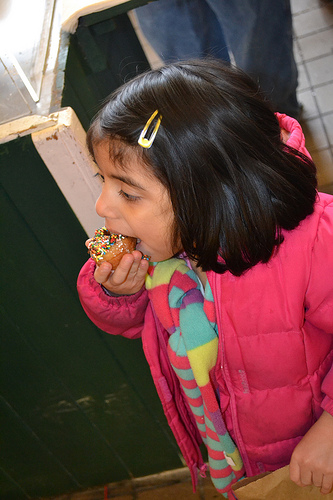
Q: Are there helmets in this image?
A: No, there are no helmets.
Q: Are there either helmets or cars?
A: No, there are no helmets or cars.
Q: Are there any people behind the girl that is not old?
A: Yes, there is a person behind the girl.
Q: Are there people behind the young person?
A: Yes, there is a person behind the girl.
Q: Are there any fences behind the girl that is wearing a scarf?
A: No, there is a person behind the girl.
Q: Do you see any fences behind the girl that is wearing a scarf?
A: No, there is a person behind the girl.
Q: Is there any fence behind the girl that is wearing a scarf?
A: No, there is a person behind the girl.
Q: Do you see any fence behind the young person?
A: No, there is a person behind the girl.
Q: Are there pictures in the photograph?
A: No, there are no pictures.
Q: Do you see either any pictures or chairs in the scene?
A: No, there are no pictures or chairs.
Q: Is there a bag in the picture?
A: Yes, there is a bag.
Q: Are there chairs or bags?
A: Yes, there is a bag.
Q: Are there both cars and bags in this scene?
A: No, there is a bag but no cars.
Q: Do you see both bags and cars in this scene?
A: No, there is a bag but no cars.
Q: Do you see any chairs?
A: No, there are no chairs.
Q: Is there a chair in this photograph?
A: No, there are no chairs.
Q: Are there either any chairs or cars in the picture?
A: No, there are no chairs or cars.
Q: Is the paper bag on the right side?
A: Yes, the bag is on the right of the image.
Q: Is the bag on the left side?
A: No, the bag is on the right of the image.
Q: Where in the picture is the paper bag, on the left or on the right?
A: The bag is on the right of the image.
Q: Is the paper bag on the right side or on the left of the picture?
A: The bag is on the right of the image.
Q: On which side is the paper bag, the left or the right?
A: The bag is on the right of the image.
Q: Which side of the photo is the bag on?
A: The bag is on the right of the image.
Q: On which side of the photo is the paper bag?
A: The bag is on the right of the image.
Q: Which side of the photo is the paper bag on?
A: The bag is on the right of the image.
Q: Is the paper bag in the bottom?
A: Yes, the bag is in the bottom of the image.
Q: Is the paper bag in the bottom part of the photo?
A: Yes, the bag is in the bottom of the image.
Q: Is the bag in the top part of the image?
A: No, the bag is in the bottom of the image.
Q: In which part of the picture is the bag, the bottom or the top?
A: The bag is in the bottom of the image.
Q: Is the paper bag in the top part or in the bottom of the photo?
A: The bag is in the bottom of the image.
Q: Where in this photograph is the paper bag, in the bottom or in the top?
A: The bag is in the bottom of the image.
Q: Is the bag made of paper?
A: Yes, the bag is made of paper.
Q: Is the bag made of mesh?
A: No, the bag is made of paper.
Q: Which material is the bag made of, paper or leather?
A: The bag is made of paper.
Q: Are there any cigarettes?
A: No, there are no cigarettes.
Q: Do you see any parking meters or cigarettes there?
A: No, there are no cigarettes or parking meters.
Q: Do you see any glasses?
A: No, there are no glasses.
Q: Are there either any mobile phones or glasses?
A: No, there are no glasses or mobile phones.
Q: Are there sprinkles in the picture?
A: Yes, there are sprinkles.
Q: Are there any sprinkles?
A: Yes, there are sprinkles.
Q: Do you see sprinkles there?
A: Yes, there are sprinkles.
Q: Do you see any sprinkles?
A: Yes, there are sprinkles.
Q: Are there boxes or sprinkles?
A: Yes, there are sprinkles.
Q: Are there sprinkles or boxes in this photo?
A: Yes, there are sprinkles.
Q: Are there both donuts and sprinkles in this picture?
A: Yes, there are both sprinkles and a donut.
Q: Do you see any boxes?
A: No, there are no boxes.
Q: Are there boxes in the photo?
A: No, there are no boxes.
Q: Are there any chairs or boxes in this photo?
A: No, there are no boxes or chairs.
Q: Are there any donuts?
A: Yes, there is a donut.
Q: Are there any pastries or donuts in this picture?
A: Yes, there is a donut.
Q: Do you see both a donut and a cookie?
A: No, there is a donut but no cookies.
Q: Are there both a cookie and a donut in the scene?
A: No, there is a donut but no cookies.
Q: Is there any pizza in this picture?
A: No, there are no pizzas.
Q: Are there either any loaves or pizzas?
A: No, there are no pizzas or loaves.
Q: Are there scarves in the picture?
A: Yes, there is a scarf.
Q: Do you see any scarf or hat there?
A: Yes, there is a scarf.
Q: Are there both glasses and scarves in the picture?
A: No, there is a scarf but no glasses.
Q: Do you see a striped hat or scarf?
A: Yes, there is a striped scarf.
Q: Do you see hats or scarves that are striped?
A: Yes, the scarf is striped.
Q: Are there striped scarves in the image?
A: Yes, there is a striped scarf.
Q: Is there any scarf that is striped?
A: Yes, there is a scarf that is striped.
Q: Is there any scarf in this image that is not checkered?
A: Yes, there is a striped scarf.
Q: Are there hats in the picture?
A: No, there are no hats.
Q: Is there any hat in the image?
A: No, there are no hats.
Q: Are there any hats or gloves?
A: No, there are no hats or gloves.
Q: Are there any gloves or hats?
A: No, there are no hats or gloves.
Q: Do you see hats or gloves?
A: No, there are no hats or gloves.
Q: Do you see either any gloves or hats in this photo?
A: No, there are no hats or gloves.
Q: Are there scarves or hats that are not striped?
A: No, there is a scarf but it is striped.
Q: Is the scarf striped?
A: Yes, the scarf is striped.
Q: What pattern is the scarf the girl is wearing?
A: The scarf is striped.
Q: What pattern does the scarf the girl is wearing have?
A: The scarf has striped pattern.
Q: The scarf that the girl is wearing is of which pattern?
A: The scarf is striped.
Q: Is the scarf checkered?
A: No, the scarf is striped.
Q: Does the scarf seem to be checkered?
A: No, the scarf is striped.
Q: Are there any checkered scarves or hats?
A: No, there is a scarf but it is striped.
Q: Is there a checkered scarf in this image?
A: No, there is a scarf but it is striped.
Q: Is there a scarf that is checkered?
A: No, there is a scarf but it is striped.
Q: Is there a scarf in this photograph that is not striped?
A: No, there is a scarf but it is striped.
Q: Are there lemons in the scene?
A: No, there are no lemons.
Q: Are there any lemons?
A: No, there are no lemons.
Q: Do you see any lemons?
A: No, there are no lemons.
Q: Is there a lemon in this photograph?
A: No, there are no lemons.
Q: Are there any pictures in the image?
A: No, there are no pictures.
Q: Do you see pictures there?
A: No, there are no pictures.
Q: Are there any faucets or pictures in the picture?
A: No, there are no pictures or faucets.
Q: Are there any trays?
A: No, there are no trays.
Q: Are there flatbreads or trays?
A: No, there are no trays or flatbreads.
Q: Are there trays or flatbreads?
A: No, there are no trays or flatbreads.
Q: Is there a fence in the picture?
A: No, there are no fences.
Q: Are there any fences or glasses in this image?
A: No, there are no fences or glasses.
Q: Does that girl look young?
A: Yes, the girl is young.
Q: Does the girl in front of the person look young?
A: Yes, the girl is young.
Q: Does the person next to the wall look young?
A: Yes, the girl is young.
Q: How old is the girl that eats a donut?
A: The girl is young.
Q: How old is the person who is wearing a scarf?
A: The girl is young.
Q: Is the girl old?
A: No, the girl is young.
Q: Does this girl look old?
A: No, the girl is young.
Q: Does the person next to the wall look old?
A: No, the girl is young.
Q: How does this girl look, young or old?
A: The girl is young.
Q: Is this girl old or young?
A: The girl is young.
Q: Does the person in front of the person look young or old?
A: The girl is young.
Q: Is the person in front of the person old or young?
A: The girl is young.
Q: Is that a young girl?
A: Yes, that is a young girl.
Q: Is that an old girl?
A: No, that is a young girl.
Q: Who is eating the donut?
A: The girl is eating the donut.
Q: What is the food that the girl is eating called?
A: The food is a donut.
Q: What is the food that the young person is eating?
A: The food is a donut.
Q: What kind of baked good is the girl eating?
A: The girl is eating a donut.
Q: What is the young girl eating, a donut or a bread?
A: The girl is eating a donut.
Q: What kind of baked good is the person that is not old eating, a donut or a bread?
A: The girl is eating a donut.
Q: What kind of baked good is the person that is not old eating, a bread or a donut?
A: The girl is eating a donut.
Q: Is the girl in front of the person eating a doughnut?
A: Yes, the girl is eating a doughnut.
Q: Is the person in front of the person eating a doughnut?
A: Yes, the girl is eating a doughnut.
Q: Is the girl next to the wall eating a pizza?
A: No, the girl is eating a doughnut.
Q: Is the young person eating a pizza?
A: No, the girl is eating a doughnut.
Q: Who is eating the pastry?
A: The girl is eating the pastry.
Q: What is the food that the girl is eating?
A: The food is a pastry.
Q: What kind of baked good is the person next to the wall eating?
A: The girl is eating a pastry.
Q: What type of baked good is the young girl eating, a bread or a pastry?
A: The girl is eating a pastry.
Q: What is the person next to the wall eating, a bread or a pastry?
A: The girl is eating a pastry.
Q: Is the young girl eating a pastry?
A: Yes, the girl is eating a pastry.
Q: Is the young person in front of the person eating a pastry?
A: Yes, the girl is eating a pastry.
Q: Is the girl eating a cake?
A: No, the girl is eating a pastry.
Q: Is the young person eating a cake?
A: No, the girl is eating a pastry.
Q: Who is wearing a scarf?
A: The girl is wearing a scarf.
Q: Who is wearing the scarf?
A: The girl is wearing a scarf.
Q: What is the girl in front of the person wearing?
A: The girl is wearing a scarf.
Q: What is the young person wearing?
A: The girl is wearing a scarf.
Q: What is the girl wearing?
A: The girl is wearing a scarf.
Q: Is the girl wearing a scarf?
A: Yes, the girl is wearing a scarf.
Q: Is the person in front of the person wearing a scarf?
A: Yes, the girl is wearing a scarf.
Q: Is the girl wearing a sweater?
A: No, the girl is wearing a scarf.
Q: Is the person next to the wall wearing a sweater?
A: No, the girl is wearing a scarf.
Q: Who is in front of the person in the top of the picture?
A: The girl is in front of the person.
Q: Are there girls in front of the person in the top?
A: Yes, there is a girl in front of the person.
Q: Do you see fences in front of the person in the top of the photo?
A: No, there is a girl in front of the person.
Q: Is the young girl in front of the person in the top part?
A: Yes, the girl is in front of the person.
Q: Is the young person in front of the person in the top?
A: Yes, the girl is in front of the person.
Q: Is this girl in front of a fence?
A: No, the girl is in front of the person.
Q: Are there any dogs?
A: No, there are no dogs.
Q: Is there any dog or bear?
A: No, there are no dogs or bears.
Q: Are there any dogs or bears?
A: No, there are no dogs or bears.